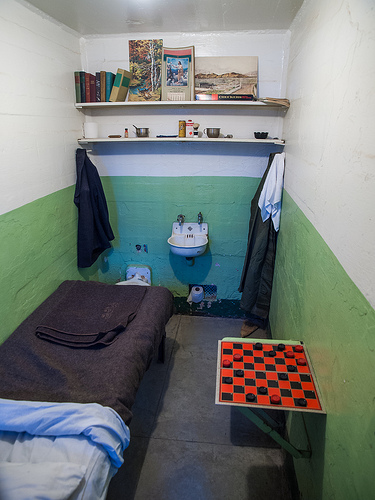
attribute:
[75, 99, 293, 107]
shelf — top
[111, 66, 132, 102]
book — shelved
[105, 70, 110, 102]
book — shelved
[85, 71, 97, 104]
book — shelved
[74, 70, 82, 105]
book — shelved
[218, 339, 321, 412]
board — red, black, checkered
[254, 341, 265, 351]
checker — black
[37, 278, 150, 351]
blanket — black, folded, gray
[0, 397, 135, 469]
sheet — blue, turned down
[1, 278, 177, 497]
bed — made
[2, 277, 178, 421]
blanket — grey, gray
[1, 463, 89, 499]
pillow case — blue, white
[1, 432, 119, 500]
sheet — blue, white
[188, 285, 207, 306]
paper — toilet, white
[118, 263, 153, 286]
toilet — white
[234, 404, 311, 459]
support — metal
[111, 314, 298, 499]
floor — gray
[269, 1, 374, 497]
wall — white, green, painted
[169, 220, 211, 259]
sink — white, empty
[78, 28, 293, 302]
wall — green, white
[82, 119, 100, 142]
paper — roll, toilet, white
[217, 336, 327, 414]
checkerboard — red, black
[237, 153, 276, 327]
coat — hanging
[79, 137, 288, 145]
shelf — bottom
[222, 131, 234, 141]
brush — shaving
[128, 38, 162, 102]
picture — colored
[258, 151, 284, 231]
towel — hanging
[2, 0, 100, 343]
wall — green, white